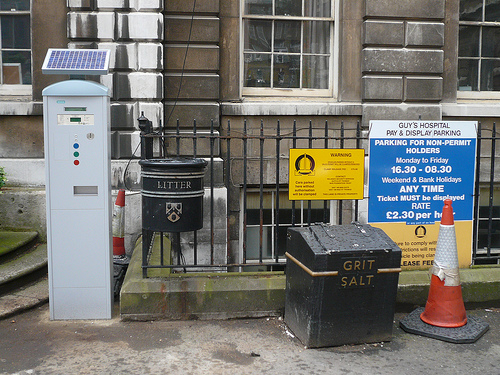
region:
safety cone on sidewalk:
[402, 185, 499, 353]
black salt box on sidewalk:
[274, 217, 416, 355]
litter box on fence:
[129, 150, 225, 242]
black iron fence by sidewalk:
[210, 123, 276, 275]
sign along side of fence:
[371, 110, 491, 207]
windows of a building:
[235, 5, 347, 104]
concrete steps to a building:
[0, 229, 45, 327]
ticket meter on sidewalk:
[25, 76, 130, 331]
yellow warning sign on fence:
[284, 143, 372, 202]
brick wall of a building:
[374, 7, 444, 109]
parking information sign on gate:
[365, 115, 484, 275]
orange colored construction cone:
[405, 187, 489, 347]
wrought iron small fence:
[212, 122, 274, 271]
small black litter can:
[130, 150, 216, 240]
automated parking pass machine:
[31, 37, 120, 331]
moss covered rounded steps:
[3, 224, 40, 266]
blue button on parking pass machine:
[64, 138, 87, 150]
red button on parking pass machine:
[72, 157, 79, 168]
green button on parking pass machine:
[72, 149, 79, 159]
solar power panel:
[34, 40, 113, 77]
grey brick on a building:
[396, 73, 452, 105]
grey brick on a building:
[354, 71, 408, 104]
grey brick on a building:
[354, 44, 449, 76]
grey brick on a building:
[396, 18, 456, 48]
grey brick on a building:
[357, 16, 409, 51]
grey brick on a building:
[362, 0, 447, 20]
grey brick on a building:
[163, 96, 224, 129]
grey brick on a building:
[158, 70, 225, 102]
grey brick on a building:
[160, 10, 226, 44]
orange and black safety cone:
[394, 192, 496, 354]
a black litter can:
[137, 156, 207, 235]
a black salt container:
[275, 216, 405, 352]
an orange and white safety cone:
[405, 197, 486, 347]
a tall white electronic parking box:
[35, 80, 116, 325]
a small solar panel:
[40, 45, 105, 75]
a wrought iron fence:
[125, 110, 495, 272]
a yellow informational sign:
[281, 145, 362, 200]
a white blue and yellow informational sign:
[367, 112, 472, 262]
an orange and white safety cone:
[109, 184, 131, 256]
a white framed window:
[240, 3, 342, 97]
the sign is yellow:
[285, 135, 398, 225]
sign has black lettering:
[289, 146, 364, 206]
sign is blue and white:
[363, 109, 489, 274]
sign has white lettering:
[375, 135, 482, 238]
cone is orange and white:
[418, 196, 487, 340]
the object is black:
[279, 209, 407, 368]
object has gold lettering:
[336, 247, 373, 301]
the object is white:
[40, 77, 140, 324]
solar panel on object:
[38, 38, 112, 85]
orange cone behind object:
[113, 173, 140, 281]